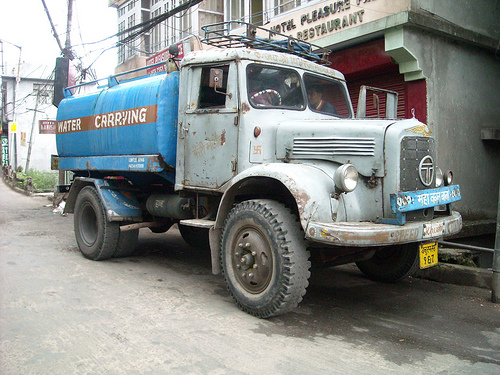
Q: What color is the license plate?
A: Yelloq.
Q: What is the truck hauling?
A: Water.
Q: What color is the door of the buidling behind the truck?
A: Red.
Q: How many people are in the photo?
A: Two.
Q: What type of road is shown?
A: Worn asphalt.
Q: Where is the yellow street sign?
A: To the far left behind the back of the truck.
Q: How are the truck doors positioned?
A: One is closed and one is open.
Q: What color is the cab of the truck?
A: Grey.